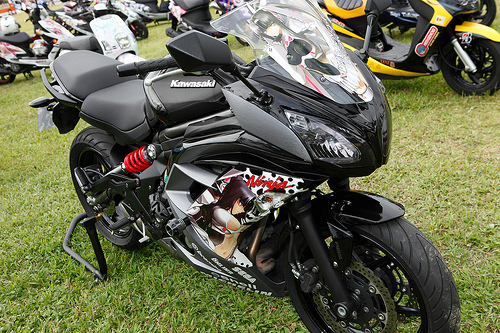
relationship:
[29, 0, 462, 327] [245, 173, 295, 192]
motorcycle has word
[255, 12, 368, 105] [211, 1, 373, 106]
girl on windshield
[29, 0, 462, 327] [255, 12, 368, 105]
motorcycle has girl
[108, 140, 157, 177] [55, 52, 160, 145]
shock on seat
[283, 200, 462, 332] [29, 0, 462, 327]
wheel of motorcycle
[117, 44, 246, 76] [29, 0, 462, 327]
handle bar of motorcycle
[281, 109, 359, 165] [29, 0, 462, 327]
light on motorcycle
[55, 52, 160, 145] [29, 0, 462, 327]
seat on motorcycle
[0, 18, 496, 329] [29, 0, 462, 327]
grass under motorcycle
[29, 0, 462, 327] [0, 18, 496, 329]
motorcycle on grass